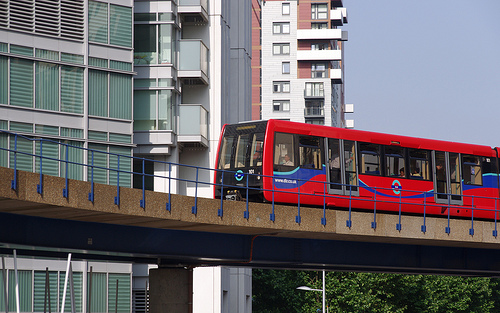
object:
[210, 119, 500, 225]
train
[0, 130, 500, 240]
railing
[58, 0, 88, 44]
blinds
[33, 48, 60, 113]
curtains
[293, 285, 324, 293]
light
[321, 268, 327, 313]
pole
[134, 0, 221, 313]
apartments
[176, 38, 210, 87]
balconies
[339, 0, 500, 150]
sky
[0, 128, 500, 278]
bridge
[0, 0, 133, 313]
building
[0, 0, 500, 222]
background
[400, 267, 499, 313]
trees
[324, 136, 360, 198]
doors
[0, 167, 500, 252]
track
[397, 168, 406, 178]
passenger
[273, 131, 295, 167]
windows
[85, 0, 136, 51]
windows